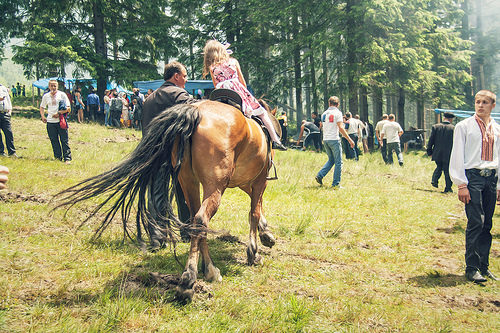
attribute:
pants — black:
[459, 167, 493, 287]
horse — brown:
[132, 90, 283, 313]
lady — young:
[186, 35, 235, 78]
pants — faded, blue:
[313, 139, 349, 185]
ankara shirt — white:
[39, 90, 75, 130]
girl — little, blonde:
[193, 22, 266, 143]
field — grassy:
[25, 264, 170, 326]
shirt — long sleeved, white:
[450, 121, 485, 162]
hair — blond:
[192, 50, 227, 64]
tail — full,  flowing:
[62, 111, 184, 245]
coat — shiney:
[202, 106, 283, 166]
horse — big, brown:
[174, 122, 266, 205]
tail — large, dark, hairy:
[74, 123, 175, 243]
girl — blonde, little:
[192, 50, 299, 159]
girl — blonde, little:
[201, 51, 284, 154]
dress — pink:
[224, 99, 264, 100]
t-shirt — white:
[32, 105, 63, 120]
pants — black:
[44, 149, 74, 171]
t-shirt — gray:
[143, 101, 163, 123]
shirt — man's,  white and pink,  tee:
[446, 114, 488, 184]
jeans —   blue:
[465, 169, 490, 275]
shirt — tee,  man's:
[319, 105, 342, 141]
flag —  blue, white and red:
[319, 113, 334, 123]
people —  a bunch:
[72, 85, 145, 129]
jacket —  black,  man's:
[426, 123, 451, 154]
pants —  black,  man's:
[430, 159, 451, 191]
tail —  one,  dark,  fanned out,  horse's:
[45, 101, 215, 256]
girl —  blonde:
[202, 35, 291, 151]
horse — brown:
[48, 97, 274, 303]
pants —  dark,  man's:
[466, 166, 498, 274]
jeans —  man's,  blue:
[314, 137, 339, 183]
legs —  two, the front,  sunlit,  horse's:
[244, 181, 274, 263]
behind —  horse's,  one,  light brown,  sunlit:
[172, 100, 228, 173]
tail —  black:
[48, 100, 201, 250]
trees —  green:
[227, 0, 474, 122]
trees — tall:
[0, 0, 484, 150]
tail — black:
[47, 102, 197, 264]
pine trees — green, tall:
[344, 27, 436, 114]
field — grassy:
[333, 184, 386, 293]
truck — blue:
[137, 77, 215, 98]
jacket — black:
[425, 120, 454, 160]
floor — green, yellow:
[1, 112, 498, 326]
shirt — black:
[301, 121, 321, 133]